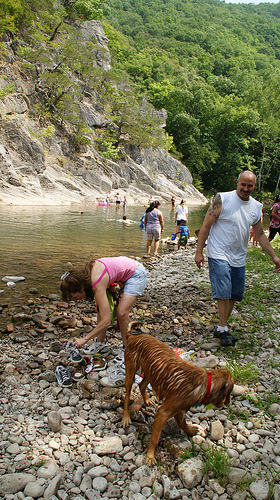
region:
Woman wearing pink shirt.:
[52, 230, 155, 366]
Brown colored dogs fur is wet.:
[114, 309, 240, 469]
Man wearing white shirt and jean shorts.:
[190, 156, 279, 351]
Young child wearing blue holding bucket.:
[167, 211, 194, 259]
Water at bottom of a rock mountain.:
[5, 1, 213, 237]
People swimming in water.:
[67, 187, 173, 254]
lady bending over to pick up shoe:
[43, 244, 164, 371]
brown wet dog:
[110, 335, 247, 474]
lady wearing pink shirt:
[67, 251, 158, 302]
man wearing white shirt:
[198, 178, 269, 281]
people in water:
[95, 186, 138, 223]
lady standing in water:
[134, 188, 174, 257]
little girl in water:
[169, 214, 198, 262]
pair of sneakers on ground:
[23, 327, 86, 387]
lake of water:
[1, 205, 237, 301]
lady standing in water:
[169, 194, 201, 228]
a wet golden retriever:
[122, 319, 234, 467]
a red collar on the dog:
[203, 370, 212, 404]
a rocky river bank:
[0, 275, 55, 499]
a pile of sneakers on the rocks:
[54, 338, 105, 388]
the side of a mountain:
[0, 0, 277, 169]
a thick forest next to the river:
[119, 1, 279, 169]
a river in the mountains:
[0, 202, 204, 258]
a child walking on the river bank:
[171, 219, 190, 252]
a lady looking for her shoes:
[60, 255, 147, 360]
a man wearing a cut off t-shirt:
[195, 171, 279, 347]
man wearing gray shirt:
[190, 160, 278, 352]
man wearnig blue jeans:
[198, 170, 270, 352]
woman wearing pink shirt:
[58, 260, 154, 332]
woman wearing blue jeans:
[56, 236, 142, 332]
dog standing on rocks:
[126, 316, 250, 470]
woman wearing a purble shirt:
[142, 196, 166, 264]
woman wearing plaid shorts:
[144, 200, 160, 258]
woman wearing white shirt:
[170, 196, 188, 230]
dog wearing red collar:
[126, 324, 240, 462]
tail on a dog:
[118, 320, 162, 340]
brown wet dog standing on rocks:
[118, 317, 236, 472]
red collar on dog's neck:
[201, 366, 212, 409]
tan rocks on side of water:
[0, 235, 276, 499]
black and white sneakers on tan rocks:
[44, 336, 86, 391]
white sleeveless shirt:
[203, 186, 264, 268]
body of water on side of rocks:
[0, 196, 278, 333]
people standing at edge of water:
[137, 192, 193, 256]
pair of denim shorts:
[204, 253, 248, 305]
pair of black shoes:
[208, 323, 240, 349]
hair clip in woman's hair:
[55, 267, 73, 281]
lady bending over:
[42, 250, 167, 367]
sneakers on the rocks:
[40, 339, 96, 396]